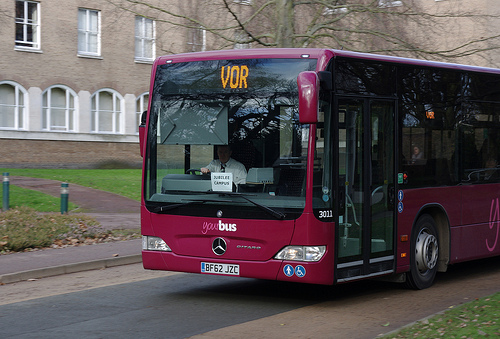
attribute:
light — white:
[141, 235, 170, 252]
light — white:
[275, 245, 325, 262]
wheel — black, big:
[405, 210, 442, 290]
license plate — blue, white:
[198, 260, 241, 275]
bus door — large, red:
[326, 90, 402, 275]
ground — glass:
[401, 131, 445, 171]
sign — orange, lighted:
[214, 62, 249, 89]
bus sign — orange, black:
[209, 61, 256, 98]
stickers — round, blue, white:
[281, 265, 313, 279]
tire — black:
[403, 217, 459, 277]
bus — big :
[85, 22, 466, 294]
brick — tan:
[57, 58, 69, 64]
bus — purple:
[120, 18, 498, 314]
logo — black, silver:
[208, 235, 226, 257]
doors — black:
[326, 97, 399, 283]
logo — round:
[211, 240, 233, 261]